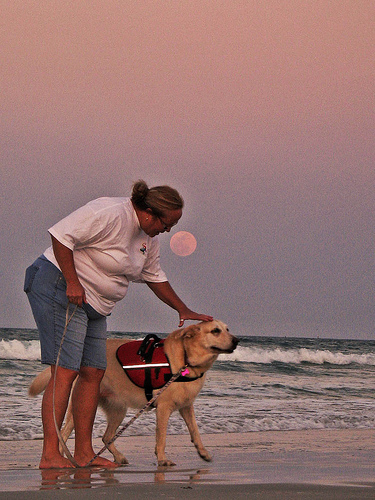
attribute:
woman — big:
[61, 129, 172, 308]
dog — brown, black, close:
[153, 308, 258, 406]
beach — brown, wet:
[28, 200, 373, 486]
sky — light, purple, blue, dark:
[30, 9, 333, 170]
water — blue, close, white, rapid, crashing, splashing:
[266, 328, 329, 424]